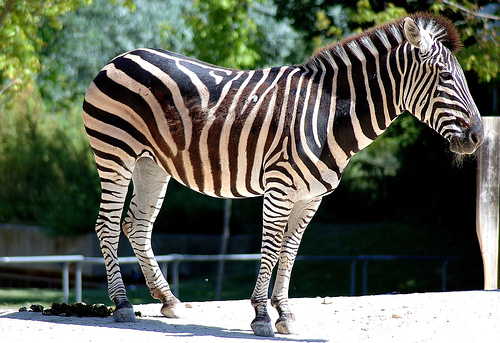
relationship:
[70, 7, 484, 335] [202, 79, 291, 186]
zebra with stripes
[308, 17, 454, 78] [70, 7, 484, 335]
mane of zebra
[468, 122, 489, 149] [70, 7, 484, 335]
nose of zebra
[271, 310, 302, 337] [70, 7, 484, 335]
hoof of zebra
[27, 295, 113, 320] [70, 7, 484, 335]
droppings of zebra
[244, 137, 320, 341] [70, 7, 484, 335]
leg of zebra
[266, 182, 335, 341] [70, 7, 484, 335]
leg of zebra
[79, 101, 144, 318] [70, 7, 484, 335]
leg of zebra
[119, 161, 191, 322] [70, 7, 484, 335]
leg of zebra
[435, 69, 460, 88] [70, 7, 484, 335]
eye of zebra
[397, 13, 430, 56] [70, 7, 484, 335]
ear of zebra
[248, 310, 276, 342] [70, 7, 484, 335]
hoof of zebra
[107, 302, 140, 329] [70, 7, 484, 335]
hoof of zebra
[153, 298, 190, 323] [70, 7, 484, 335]
hoof of zebra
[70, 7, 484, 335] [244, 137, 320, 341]
zebra has leg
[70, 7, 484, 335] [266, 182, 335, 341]
zebra has leg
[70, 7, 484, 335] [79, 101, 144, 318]
zebra has leg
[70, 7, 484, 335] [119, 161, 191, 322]
zebra has leg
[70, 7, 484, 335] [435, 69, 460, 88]
zebra has eye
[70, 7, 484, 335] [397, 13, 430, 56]
zebra has ear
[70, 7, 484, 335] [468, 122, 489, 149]
zebra has nose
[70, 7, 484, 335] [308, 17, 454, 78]
zebra has mane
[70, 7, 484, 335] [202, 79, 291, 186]
zebra has stripes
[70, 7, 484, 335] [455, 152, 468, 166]
zebra has whiskers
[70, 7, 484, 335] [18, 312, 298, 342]
zebra has shadow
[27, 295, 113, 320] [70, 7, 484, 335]
poop of zebra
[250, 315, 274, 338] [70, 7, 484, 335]
hoof of zebra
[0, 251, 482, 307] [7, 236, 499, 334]
pen around pen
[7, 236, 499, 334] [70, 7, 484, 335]
pen of zebra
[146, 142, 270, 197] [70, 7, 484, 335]
belly of zebra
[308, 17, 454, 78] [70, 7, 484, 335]
mane on zebra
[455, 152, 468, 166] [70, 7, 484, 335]
hair from zebra